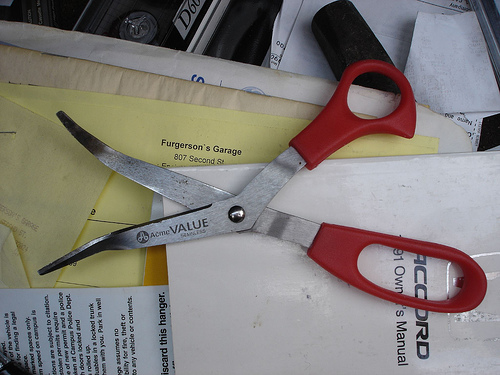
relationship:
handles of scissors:
[290, 60, 487, 312] [36, 61, 490, 312]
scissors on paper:
[9, 49, 496, 360] [156, 147, 494, 367]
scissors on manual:
[36, 61, 490, 312] [180, 265, 348, 358]